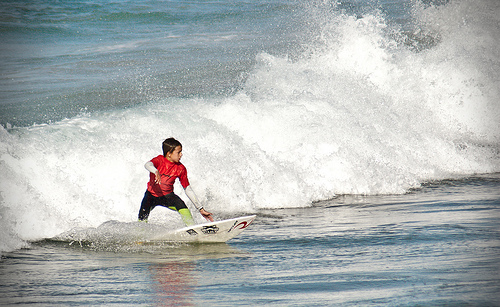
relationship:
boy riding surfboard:
[136, 133, 217, 229] [144, 208, 256, 246]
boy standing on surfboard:
[136, 133, 217, 229] [152, 211, 256, 245]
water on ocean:
[246, 139, 497, 305] [2, 3, 497, 303]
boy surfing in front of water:
[136, 133, 217, 229] [246, 139, 497, 305]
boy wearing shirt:
[136, 133, 217, 229] [145, 152, 191, 201]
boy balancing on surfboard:
[136, 133, 217, 229] [143, 210, 253, 252]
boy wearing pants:
[136, 133, 217, 229] [134, 189, 199, 230]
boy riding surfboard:
[136, 136, 217, 229] [152, 211, 256, 245]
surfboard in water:
[152, 211, 256, 245] [0, 0, 496, 305]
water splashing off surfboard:
[48, 221, 202, 256] [152, 211, 254, 247]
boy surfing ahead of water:
[136, 136, 217, 229] [246, 139, 497, 305]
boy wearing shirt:
[136, 136, 217, 229] [145, 151, 189, 197]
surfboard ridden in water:
[152, 211, 256, 245] [0, 0, 496, 305]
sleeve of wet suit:
[181, 185, 202, 214] [137, 156, 203, 227]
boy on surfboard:
[136, 133, 217, 229] [152, 211, 256, 245]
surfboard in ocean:
[152, 211, 256, 245] [2, 3, 497, 303]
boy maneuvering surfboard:
[136, 136, 217, 229] [152, 211, 256, 245]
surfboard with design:
[152, 211, 256, 245] [185, 218, 247, 234]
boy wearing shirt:
[136, 136, 217, 229] [144, 156, 190, 196]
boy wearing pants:
[136, 136, 217, 229] [137, 189, 193, 227]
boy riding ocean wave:
[136, 133, 217, 229] [0, 2, 498, 254]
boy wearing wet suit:
[136, 136, 217, 229] [137, 156, 203, 227]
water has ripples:
[0, 0, 496, 305] [266, 216, 477, 272]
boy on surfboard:
[136, 136, 217, 229] [143, 214, 257, 244]